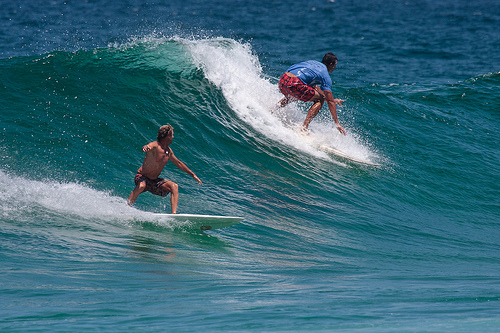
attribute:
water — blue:
[2, 0, 499, 331]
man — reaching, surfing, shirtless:
[124, 120, 203, 214]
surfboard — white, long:
[154, 212, 247, 229]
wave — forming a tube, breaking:
[3, 30, 391, 261]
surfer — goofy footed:
[267, 52, 349, 137]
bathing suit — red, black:
[276, 73, 317, 105]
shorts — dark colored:
[133, 173, 170, 197]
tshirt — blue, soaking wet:
[282, 59, 334, 93]